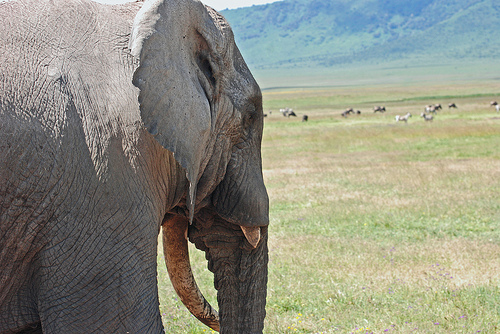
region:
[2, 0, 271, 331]
Elephant facing away from the camera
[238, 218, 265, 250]
One small tusk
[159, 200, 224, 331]
One large tusk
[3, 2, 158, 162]
Bright patch of sunshine on elephant's back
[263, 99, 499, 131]
Herd of grazing animals in background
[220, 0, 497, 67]
Tree covered hills behind herd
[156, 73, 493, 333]
Savanna grasses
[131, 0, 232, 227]
Right ear in partial sunlight, partial shade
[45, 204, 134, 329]
Gray wrinkly skin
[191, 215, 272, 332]
Underside of trunk visible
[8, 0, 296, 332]
gray and white elephant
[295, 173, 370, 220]
short green and brown grass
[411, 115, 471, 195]
short green and brown grass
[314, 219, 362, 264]
short green and brown grass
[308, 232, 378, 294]
short green and brown grass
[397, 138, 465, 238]
short green and brown grass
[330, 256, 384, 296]
short green and brown grass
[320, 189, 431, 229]
short green and brown grass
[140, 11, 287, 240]
head of an elephant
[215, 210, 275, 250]
trunk of an elephant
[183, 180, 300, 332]
nose of an elephant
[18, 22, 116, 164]
body of an elephant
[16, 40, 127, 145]
skin of an elephant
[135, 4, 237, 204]
ear of an elephant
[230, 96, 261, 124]
eye of an elephant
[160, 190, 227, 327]
trunk of an elephant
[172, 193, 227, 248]
mouth of an elephant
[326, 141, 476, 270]
a grassy plain field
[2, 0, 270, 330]
An elephant missing a tusk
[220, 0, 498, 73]
A green brush covered bluff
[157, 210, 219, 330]
A dirty elephant tusk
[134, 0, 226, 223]
A large grey elephant ear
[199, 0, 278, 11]
A small patch of sky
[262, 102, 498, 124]
Animals pasturing in the distance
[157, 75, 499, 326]
Open green and dry pasture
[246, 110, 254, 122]
The wise eye of an elephant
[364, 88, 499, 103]
Taller green grass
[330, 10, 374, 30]
A dark green bush